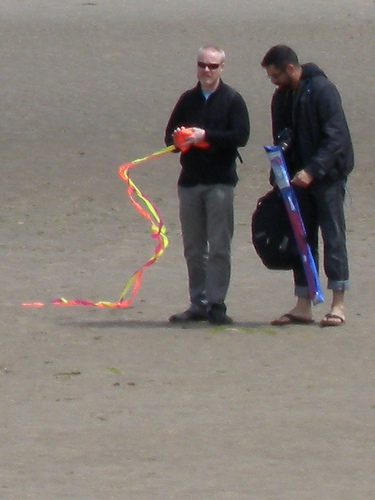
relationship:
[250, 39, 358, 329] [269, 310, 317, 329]
man wearing sandal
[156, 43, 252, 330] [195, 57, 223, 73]
man wearing sunglasses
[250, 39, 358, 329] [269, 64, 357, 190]
man wearing jacket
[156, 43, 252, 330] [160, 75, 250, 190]
man wearing sweater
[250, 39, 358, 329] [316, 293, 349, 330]
man has foot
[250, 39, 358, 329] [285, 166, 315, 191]
man has hand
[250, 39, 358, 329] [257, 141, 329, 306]
man holding object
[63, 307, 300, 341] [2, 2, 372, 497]
shadow on top of ground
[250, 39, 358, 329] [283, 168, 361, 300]
man wearing pants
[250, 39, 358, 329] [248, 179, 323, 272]
man carrying backpack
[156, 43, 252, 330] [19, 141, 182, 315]
man holding ribbon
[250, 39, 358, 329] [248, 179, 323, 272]
man holding backpack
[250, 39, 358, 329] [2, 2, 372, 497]
man standing on ground